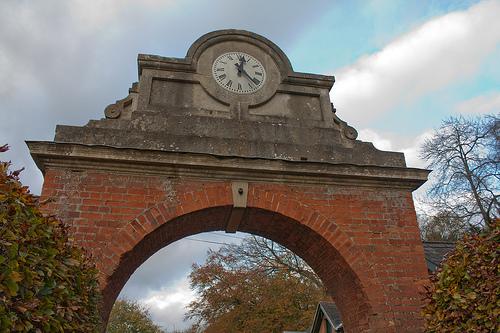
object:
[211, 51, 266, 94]
clock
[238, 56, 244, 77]
hands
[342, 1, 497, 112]
clouds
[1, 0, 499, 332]
sky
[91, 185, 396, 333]
arch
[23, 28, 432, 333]
structure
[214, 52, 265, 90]
numerals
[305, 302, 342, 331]
roof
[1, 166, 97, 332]
bushes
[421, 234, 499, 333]
bush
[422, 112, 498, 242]
tree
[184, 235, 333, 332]
tree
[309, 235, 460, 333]
house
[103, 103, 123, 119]
scrollwork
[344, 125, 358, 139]
scrollwork